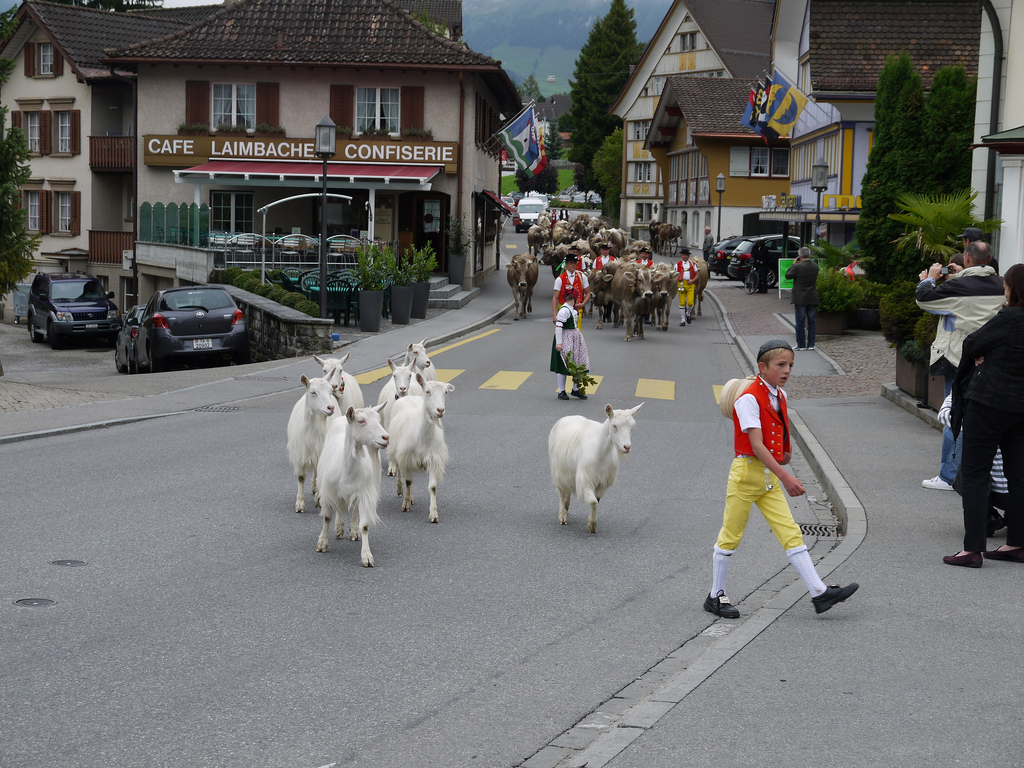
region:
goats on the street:
[270, 300, 653, 576]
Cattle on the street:
[500, 187, 709, 333]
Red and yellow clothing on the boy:
[686, 339, 860, 621]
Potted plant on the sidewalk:
[339, 236, 385, 338]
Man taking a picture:
[905, 233, 1005, 496]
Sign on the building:
[138, 124, 459, 172]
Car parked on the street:
[19, 262, 133, 354]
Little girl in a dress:
[533, 273, 610, 403]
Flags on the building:
[725, 47, 836, 153]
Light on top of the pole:
[314, 112, 340, 160]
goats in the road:
[286, 343, 645, 565]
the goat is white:
[544, 398, 649, 542]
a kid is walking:
[705, 343, 860, 620]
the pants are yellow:
[716, 460, 800, 558]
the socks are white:
[708, 546, 825, 598]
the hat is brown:
[708, 374, 751, 416]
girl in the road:
[555, 287, 598, 404]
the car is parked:
[140, 290, 251, 373]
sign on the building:
[141, 132, 455, 172]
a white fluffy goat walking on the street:
[307, 401, 402, 570]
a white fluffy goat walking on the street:
[283, 379, 347, 506]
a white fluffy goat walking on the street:
[310, 349, 372, 425]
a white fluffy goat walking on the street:
[402, 342, 442, 381]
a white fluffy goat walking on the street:
[375, 355, 430, 420]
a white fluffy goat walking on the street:
[384, 371, 461, 523]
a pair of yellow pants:
[716, 455, 808, 548]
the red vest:
[728, 373, 792, 471]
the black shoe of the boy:
[699, 589, 735, 619]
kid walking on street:
[648, 320, 868, 556]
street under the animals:
[132, 598, 452, 736]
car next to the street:
[95, 228, 298, 419]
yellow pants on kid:
[694, 474, 813, 557]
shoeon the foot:
[755, 559, 899, 665]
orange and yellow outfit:
[629, 307, 892, 590]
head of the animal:
[562, 386, 664, 485]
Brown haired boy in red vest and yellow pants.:
[705, 337, 861, 620]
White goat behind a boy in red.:
[545, 401, 647, 535]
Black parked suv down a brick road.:
[25, 273, 124, 350]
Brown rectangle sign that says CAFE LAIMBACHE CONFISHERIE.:
[144, 132, 459, 172]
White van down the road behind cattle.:
[515, 195, 548, 230]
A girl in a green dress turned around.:
[546, 289, 591, 400]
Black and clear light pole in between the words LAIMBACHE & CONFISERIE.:
[313, 113, 339, 313]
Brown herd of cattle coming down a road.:
[507, 215, 713, 340]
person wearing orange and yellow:
[647, 303, 881, 545]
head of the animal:
[582, 372, 681, 481]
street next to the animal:
[438, 538, 584, 643]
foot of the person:
[783, 560, 908, 646]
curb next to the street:
[607, 642, 738, 748]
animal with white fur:
[474, 366, 672, 563]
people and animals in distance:
[474, 200, 738, 353]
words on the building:
[101, 34, 471, 225]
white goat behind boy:
[551, 403, 646, 532]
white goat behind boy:
[314, 394, 394, 571]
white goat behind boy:
[373, 374, 460, 525]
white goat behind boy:
[282, 374, 345, 515]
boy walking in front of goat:
[699, 338, 852, 620]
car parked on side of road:
[24, 269, 123, 351]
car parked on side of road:
[109, 303, 148, 373]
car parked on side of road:
[129, 286, 258, 373]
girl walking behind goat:
[551, 286, 592, 400]